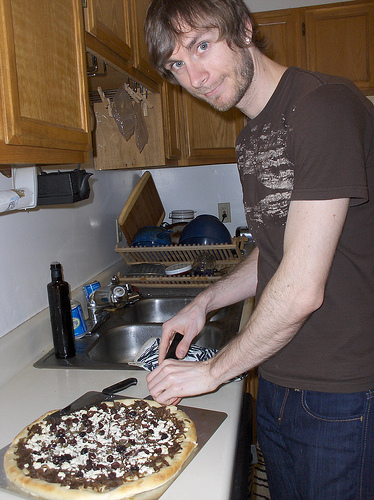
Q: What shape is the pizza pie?
A: Round.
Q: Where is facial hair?
A: On man's face.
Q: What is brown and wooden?
A: Cabinets.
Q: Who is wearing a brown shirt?
A: The guy.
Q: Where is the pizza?
A: On a countertop.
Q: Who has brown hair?
A: The man.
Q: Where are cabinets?
A: Above the sink.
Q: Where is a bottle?
A: On the sink.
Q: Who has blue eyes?
A: The guy.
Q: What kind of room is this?
A: Kitchen.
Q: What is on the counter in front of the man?
A: Pizza.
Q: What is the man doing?
A: Holding the handle of a pizza pan.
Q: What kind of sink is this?
A: Double sink.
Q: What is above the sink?
A: Wooden cabinets.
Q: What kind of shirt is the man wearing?
A: Short sleeve t-shirt.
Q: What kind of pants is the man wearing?
A: Jeans.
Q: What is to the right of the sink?
A: Dish drainer.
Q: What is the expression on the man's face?
A: Smile.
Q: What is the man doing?
A: Serving pizza.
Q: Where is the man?
A: Kitchen.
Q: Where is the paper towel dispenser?
A: Under the cabinet.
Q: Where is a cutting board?
A: Dish drainer.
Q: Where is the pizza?
A: BAKING SHEET.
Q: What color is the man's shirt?
A: Brown.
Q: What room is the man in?
A: The kitchen.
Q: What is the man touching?
A: Pizza.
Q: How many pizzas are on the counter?
A: 1.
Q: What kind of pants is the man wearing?
A: Jeans.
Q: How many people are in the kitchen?
A: 1.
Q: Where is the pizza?
A: On the counter.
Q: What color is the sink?
A: Silver.